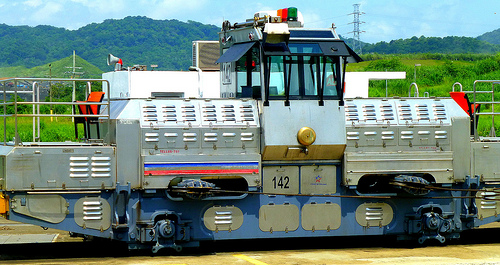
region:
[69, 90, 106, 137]
an orange and black seat on the boat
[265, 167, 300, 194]
a number on the vehicle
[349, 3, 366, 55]
a radio tower in the background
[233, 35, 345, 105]
a small area for the driver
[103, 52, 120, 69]
a horn to warn people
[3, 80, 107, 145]
a metal fence to contain the area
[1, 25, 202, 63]
a grassy mountain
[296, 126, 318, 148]
a bell on the side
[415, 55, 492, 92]
a green grassy field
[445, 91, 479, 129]
another orange and black chair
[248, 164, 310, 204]
142 on side of train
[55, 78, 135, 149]
the train has an orange chair on the right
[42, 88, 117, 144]
train with orange chair on the left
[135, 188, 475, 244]
train is blue on the bottom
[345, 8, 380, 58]
electric tower in the background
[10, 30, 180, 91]
hills with trees in background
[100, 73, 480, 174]
train is silver on top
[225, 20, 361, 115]
glass window cage on train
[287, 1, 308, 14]
green light on top of train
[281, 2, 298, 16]
red light on train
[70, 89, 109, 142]
chair is partially folded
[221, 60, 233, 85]
in vehicle window is its label '142'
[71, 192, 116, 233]
rectangular metal vents in octagonal placement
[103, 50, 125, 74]
horn atop building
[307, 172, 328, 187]
red+blue star logo on side, probably government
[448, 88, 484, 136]
another partially folded bright red canvas chair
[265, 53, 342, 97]
window has teal blue tinting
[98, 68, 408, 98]
only the tops of the windows of building vehicle are visible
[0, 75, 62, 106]
a parking lot in the far left distance, with a few vehicles in it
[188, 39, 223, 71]
industrial air conditioner atop building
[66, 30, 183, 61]
the trees are in the background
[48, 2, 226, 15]
the sky is blue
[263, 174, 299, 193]
the number is 142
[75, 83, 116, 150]
there is a red chair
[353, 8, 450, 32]
electric wires in the air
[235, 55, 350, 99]
the window is made of glass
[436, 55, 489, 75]
the trees are green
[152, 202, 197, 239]
the object is blue metallic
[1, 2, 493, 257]
its daytime in the photo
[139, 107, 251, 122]
the vents are white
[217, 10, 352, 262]
the observation tower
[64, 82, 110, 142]
an orange folding chair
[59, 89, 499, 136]
two orange folding chairs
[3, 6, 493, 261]
a car on the train tracks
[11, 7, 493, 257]
car number one hundred forty-two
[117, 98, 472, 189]
blue and red stripe on the left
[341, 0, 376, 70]
a power line tower in the distance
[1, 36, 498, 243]
air vents all over the structure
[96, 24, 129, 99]
a horn on the top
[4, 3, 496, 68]
wooded hills in the background